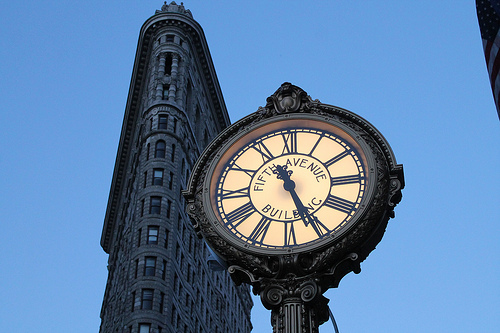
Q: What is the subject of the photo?
A: Clock.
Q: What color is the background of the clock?
A: White.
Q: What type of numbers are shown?
A: Roman numerals.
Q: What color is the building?
A: Gray.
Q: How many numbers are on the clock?
A: Twelve.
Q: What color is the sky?
A: Blue.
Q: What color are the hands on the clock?
A: Black.